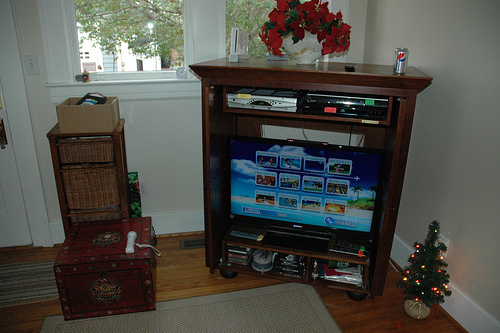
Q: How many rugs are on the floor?
A: 2.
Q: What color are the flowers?
A: Red.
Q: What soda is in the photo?
A: Pepsi.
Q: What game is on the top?
A: Wii.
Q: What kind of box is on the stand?
A: Cardboard.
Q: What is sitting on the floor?
A: Christmas tree.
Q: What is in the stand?
A: Tv.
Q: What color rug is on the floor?
A: Tan.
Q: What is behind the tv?
A: Window.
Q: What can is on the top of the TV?
A: Diet Pepsi.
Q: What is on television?
A: Video games.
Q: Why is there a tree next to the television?
A: It is Christmas Time.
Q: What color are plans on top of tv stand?
A: Red.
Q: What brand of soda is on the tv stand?
A: Pepsi.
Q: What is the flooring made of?
A: Wood.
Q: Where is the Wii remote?
A: On the red box.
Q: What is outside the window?
A: A tree and building.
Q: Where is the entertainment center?
A: In the corner.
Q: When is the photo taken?
A: Christmastime.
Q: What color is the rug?
A: Beige.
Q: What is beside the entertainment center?
A: Christmas tree.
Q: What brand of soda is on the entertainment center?
A: Pepsi.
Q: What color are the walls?
A: White.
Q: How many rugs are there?
A: Two.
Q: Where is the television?
A: Entertainment center.